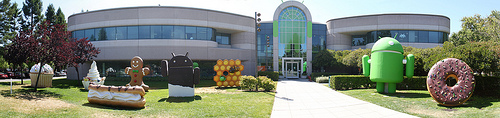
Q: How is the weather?
A: Sunny.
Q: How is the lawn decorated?
A: Figures and statues.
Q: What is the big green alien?
A: Android.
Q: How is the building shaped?
A: Round.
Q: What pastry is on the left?
A: Long john.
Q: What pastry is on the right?
A: Sprinkle donut.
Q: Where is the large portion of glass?
A: Entryway.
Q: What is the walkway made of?
A: Concrete.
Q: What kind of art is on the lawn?
A: Public art.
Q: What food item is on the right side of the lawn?
A: A donut.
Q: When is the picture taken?
A: Daytime.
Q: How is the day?
A: Sunny.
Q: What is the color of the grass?
A: Green.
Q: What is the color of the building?
A: Purple.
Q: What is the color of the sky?
A: Blue.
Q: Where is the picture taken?
A: In front of a building.